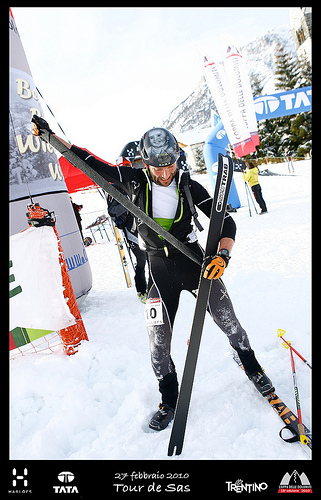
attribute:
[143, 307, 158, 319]
number — 10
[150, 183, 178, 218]
shirt — white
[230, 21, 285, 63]
peak — mountain, covered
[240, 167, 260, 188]
shirt — yellow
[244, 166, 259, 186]
shirt — yellow, long-sleeved